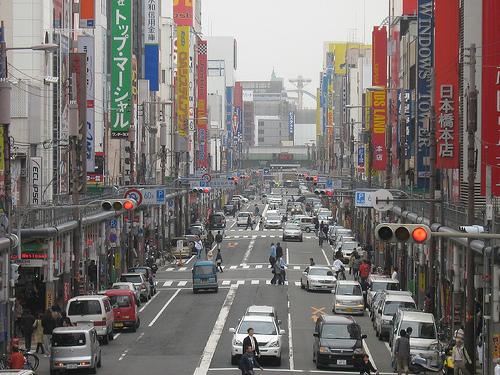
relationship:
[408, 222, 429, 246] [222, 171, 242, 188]
red light on traffic light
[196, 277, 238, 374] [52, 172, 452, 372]
traffic line on street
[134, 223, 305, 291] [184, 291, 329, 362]
people in front of car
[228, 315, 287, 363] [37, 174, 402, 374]
vehicle on road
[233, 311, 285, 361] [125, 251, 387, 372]
car on street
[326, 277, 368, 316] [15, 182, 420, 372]
car on street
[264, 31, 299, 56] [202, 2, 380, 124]
white overcast sky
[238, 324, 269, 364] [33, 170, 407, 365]
person crossing street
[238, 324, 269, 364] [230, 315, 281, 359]
person in front of car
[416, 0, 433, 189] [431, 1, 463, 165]
blue sign behind sign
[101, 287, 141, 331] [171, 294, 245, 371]
vehicle on road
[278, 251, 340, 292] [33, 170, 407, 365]
car on street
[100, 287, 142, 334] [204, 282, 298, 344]
car on street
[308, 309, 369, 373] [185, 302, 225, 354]
car on street